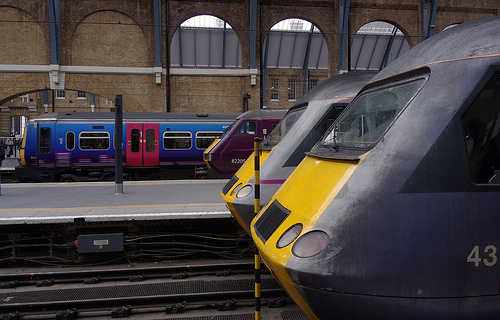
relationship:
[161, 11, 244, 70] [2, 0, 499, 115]
window on wall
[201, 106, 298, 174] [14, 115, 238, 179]
train next to car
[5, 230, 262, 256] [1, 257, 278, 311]
cable above track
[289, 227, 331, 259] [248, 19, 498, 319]
light on engine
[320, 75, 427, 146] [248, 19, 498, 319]
windshield on engine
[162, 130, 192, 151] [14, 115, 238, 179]
glass on car